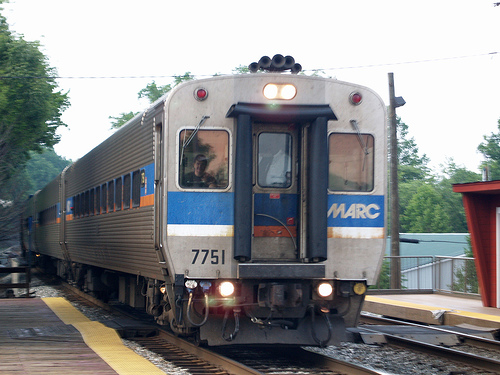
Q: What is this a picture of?
A: A train.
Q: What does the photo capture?
A: A train.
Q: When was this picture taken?
A: During daylight.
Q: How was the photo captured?
A: With a camera.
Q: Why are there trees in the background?
A: The station is in a lush area.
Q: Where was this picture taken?
A: At the train station.